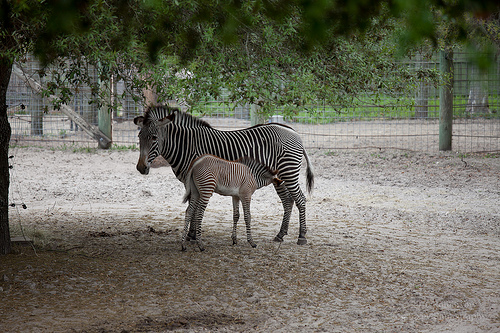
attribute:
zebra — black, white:
[130, 97, 316, 249]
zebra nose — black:
[133, 163, 151, 173]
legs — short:
[270, 177, 309, 242]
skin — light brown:
[193, 159, 253, 191]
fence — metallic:
[310, 50, 497, 149]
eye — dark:
[143, 130, 162, 146]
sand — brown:
[37, 242, 467, 331]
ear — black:
[158, 113, 176, 124]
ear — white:
[131, 115, 145, 123]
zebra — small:
[138, 79, 302, 226]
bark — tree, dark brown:
[2, 67, 14, 266]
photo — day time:
[4, 1, 499, 331]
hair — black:
[133, 100, 216, 128]